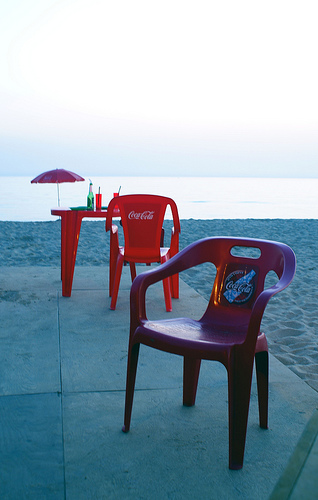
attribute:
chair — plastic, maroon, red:
[124, 233, 274, 472]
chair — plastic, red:
[105, 192, 181, 313]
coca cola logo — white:
[122, 203, 159, 235]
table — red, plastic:
[48, 208, 167, 305]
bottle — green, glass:
[86, 185, 97, 208]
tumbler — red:
[91, 193, 101, 216]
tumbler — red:
[113, 190, 125, 202]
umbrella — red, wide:
[30, 166, 86, 186]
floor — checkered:
[7, 264, 317, 497]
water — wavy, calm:
[1, 176, 303, 225]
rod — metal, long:
[56, 180, 64, 215]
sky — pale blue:
[3, 4, 315, 182]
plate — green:
[70, 205, 91, 211]